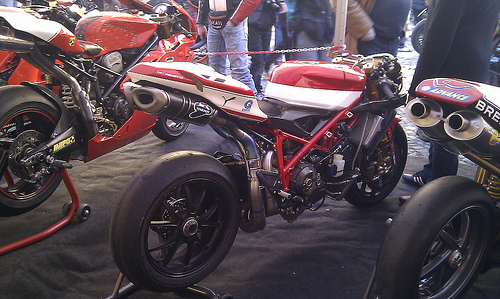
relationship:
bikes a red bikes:
[110, 49, 412, 294] [110, 49, 412, 294]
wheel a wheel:
[105, 145, 245, 297] [105, 145, 245, 297]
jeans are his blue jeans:
[205, 16, 257, 96] [200, 7, 265, 97]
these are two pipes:
[412, 97, 452, 162] [399, 96, 499, 162]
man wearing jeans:
[194, 0, 260, 96] [203, 7, 266, 86]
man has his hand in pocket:
[186, 2, 275, 117] [213, 50, 243, 90]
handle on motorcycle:
[38, 50, 98, 112] [37, 101, 385, 292]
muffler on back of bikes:
[405, 98, 484, 148] [110, 49, 412, 294]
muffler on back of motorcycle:
[405, 98, 484, 148] [370, 62, 498, 294]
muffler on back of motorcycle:
[405, 98, 484, 148] [1, 6, 200, 215]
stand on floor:
[50, 158, 98, 226] [0, 24, 498, 296]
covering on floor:
[0, 154, 500, 296] [0, 24, 498, 296]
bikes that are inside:
[110, 49, 412, 294] [2, 49, 481, 281]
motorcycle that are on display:
[370, 62, 498, 294] [15, 51, 397, 291]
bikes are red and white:
[110, 49, 412, 294] [6, 54, 471, 176]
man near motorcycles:
[194, 0, 260, 96] [5, 27, 465, 291]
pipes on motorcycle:
[390, 91, 499, 161] [370, 62, 498, 294]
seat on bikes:
[252, 95, 287, 117] [110, 49, 412, 294]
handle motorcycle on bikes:
[364, 80, 399, 107] [110, 49, 412, 294]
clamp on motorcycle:
[1, 132, 93, 253] [1, 6, 200, 215]